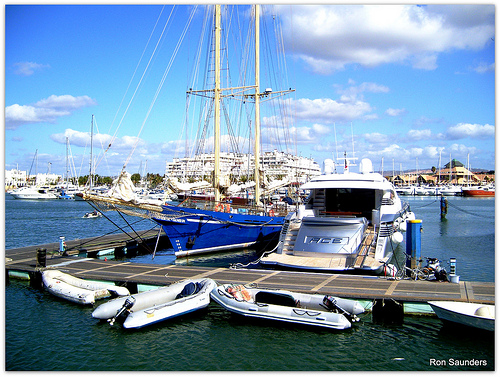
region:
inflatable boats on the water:
[87, 277, 373, 337]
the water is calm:
[111, 302, 299, 362]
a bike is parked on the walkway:
[372, 240, 450, 286]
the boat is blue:
[128, 7, 267, 262]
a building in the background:
[154, 132, 305, 180]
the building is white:
[149, 133, 312, 185]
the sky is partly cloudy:
[88, 14, 425, 161]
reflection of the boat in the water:
[172, 240, 251, 262]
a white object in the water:
[377, 342, 422, 367]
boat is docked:
[91, 277, 216, 329]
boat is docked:
[212, 281, 366, 335]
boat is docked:
[420, 295, 498, 332]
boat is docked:
[261, 158, 406, 273]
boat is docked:
[91, 2, 298, 264]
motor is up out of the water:
[104, 297, 134, 327]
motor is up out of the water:
[320, 293, 365, 324]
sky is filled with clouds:
[5, 0, 491, 170]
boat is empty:
[262, 157, 413, 275]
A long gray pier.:
[82, 248, 499, 335]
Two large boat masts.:
[182, 1, 282, 205]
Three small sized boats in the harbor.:
[41, 266, 368, 353]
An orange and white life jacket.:
[221, 284, 249, 306]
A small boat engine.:
[317, 290, 360, 331]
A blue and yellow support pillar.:
[406, 216, 426, 277]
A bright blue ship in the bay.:
[80, 169, 292, 249]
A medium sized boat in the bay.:
[268, 150, 408, 270]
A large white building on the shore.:
[156, 135, 312, 188]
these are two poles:
[212, 0, 263, 215]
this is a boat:
[210, 172, 410, 333]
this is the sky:
[5, 0, 495, 169]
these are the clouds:
[250, 0, 499, 77]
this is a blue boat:
[135, 195, 290, 264]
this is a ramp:
[4, 225, 496, 304]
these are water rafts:
[38, 265, 388, 330]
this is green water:
[2, 284, 497, 375]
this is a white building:
[162, 149, 325, 198]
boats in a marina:
[17, 121, 493, 355]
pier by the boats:
[86, 249, 486, 314]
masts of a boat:
[196, 68, 283, 160]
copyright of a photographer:
[406, 345, 492, 374]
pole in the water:
[433, 191, 451, 227]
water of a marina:
[12, 204, 65, 239]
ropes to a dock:
[158, 200, 270, 249]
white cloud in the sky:
[276, 4, 441, 75]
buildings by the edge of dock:
[389, 160, 491, 195]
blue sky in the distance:
[17, 4, 141, 59]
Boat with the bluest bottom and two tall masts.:
[75, 3, 295, 258]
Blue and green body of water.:
[6, 191, 496, 367]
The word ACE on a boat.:
[308, 236, 341, 243]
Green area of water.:
[6, 281, 491, 370]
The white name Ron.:
[428, 357, 446, 366]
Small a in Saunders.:
[453, 359, 460, 366]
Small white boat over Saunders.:
[425, 299, 495, 331]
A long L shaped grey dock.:
[6, 228, 496, 305]